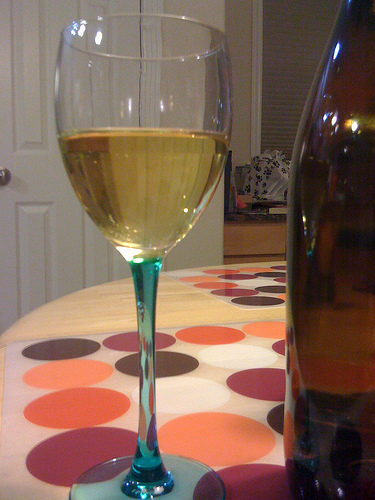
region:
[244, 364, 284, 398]
polka dot on the placemat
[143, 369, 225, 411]
polka dot on the placemat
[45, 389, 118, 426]
polka dot on the placemat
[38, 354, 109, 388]
polka dot on the placemat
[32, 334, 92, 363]
polka dot on the placemat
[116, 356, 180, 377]
polka dot on the placemat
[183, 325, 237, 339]
polka dot on the placemat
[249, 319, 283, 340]
polka dot on the placemat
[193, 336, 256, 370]
polka dot on the placemat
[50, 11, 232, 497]
wine glass on the table.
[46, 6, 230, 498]
A glass on the table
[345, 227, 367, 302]
Part of the bottle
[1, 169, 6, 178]
Part of the door knob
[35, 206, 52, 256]
Part of the door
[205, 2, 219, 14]
Part of the wall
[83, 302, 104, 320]
Part of the table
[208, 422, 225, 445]
Part of the orange circle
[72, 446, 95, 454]
Part of the red circle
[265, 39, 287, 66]
Part of the window shades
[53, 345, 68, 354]
Part of the black circle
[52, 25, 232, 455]
a wine glass on a table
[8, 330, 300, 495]
a place mat on the table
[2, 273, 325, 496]
a round table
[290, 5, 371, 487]
a wine bottle on the table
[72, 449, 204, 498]
the base of the wine glass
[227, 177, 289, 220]
a counter top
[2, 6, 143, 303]
a white door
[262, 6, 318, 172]
a window behind the counter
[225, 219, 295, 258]
a drawer under the counter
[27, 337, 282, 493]
dots on the placemat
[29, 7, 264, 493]
a glass of wine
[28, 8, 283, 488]
a glass of wine on a table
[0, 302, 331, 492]
the placemat has large spots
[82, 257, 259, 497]
the stem of the wine glass is blue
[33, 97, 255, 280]
white wine in a glass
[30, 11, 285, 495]
a wine glass with a skinny stem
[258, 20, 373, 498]
this is the wine bottle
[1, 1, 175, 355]
a white door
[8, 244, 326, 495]
the table is round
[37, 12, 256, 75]
the rim of a wine glass